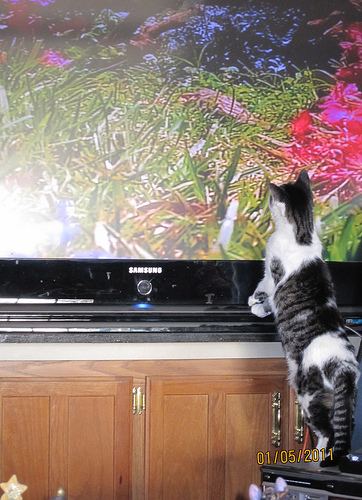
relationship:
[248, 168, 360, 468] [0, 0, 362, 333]
cat watching tv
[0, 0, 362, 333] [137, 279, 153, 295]
tv has a power button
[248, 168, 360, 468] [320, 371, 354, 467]
cat has a tail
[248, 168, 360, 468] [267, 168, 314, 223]
cat has a head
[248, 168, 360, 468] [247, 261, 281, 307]
cat has a front left leg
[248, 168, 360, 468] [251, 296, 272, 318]
cat has a front right leg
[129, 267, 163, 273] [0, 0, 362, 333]
logo on bottom of tv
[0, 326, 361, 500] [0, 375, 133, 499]
cabinet has a door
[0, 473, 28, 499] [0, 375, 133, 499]
star on door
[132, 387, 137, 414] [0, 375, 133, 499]
hinge on door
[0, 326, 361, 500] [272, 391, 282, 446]
cabinet has a handle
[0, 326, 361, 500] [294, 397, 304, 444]
cabinet has a handle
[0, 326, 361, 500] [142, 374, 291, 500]
cabinet has a door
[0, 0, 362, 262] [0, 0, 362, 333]
flowers are showing on tv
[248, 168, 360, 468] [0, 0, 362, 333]
cat looking at tv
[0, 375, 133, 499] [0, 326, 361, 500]
door on a cabinet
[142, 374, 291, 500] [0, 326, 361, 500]
door on a cabinet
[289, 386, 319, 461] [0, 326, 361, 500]
door on a cabinet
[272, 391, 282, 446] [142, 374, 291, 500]
handle on a door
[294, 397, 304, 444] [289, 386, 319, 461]
handle on a door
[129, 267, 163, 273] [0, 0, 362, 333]
logo on tv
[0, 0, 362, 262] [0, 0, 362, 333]
flowers are on tv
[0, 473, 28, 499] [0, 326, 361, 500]
star on cabinet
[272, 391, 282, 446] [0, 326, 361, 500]
handle on cabinet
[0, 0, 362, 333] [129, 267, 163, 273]
tv has a logo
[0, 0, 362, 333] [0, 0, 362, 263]
tv has a screen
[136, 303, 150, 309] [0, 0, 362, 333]
power light on tv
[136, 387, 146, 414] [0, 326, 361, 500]
hinge on cabinet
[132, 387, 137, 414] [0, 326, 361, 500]
hinge on cabinet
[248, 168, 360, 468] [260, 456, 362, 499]
cat standing on electronics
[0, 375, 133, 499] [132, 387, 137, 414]
door has a hinge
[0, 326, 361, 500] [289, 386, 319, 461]
cabinet has a door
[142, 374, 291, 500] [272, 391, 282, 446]
door has a handle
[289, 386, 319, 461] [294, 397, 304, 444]
door has a handle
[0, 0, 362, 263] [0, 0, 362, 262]
screen showing flowers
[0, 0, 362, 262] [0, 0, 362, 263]
flowers are on screen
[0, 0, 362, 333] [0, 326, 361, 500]
tv on cabinet